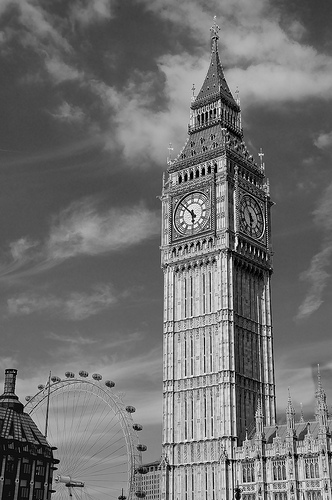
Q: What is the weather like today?
A: It is cloudy.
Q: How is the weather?
A: It is cloudy.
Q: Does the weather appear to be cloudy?
A: Yes, it is cloudy.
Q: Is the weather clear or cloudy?
A: It is cloudy.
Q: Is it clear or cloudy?
A: It is cloudy.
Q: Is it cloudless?
A: No, it is cloudy.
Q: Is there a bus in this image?
A: No, there are no buses.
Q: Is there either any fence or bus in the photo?
A: No, there are no buses or fences.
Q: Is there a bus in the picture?
A: No, there are no buses.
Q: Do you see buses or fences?
A: No, there are no buses or fences.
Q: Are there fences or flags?
A: No, there are no fences or flags.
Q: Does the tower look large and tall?
A: Yes, the tower is large and tall.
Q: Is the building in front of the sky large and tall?
A: Yes, the tower is large and tall.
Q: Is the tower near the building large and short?
A: No, the tower is large but tall.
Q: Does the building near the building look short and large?
A: No, the tower is large but tall.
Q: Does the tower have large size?
A: Yes, the tower is large.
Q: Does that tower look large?
A: Yes, the tower is large.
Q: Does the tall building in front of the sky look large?
A: Yes, the tower is large.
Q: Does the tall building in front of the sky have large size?
A: Yes, the tower is large.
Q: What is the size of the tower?
A: The tower is large.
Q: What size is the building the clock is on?
A: The tower is large.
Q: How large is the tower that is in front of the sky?
A: The tower is large.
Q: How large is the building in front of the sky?
A: The tower is large.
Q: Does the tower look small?
A: No, the tower is large.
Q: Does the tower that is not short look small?
A: No, the tower is large.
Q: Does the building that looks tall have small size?
A: No, the tower is large.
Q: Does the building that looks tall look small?
A: No, the tower is large.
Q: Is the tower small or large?
A: The tower is large.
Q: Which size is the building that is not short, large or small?
A: The tower is large.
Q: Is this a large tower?
A: Yes, this is a large tower.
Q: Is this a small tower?
A: No, this is a large tower.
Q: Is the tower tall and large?
A: Yes, the tower is tall and large.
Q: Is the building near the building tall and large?
A: Yes, the tower is tall and large.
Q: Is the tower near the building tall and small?
A: No, the tower is tall but large.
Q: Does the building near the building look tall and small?
A: No, the tower is tall but large.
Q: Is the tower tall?
A: Yes, the tower is tall.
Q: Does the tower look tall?
A: Yes, the tower is tall.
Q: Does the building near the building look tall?
A: Yes, the tower is tall.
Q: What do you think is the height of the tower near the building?
A: The tower is tall.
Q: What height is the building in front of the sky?
A: The tower is tall.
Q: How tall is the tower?
A: The tower is tall.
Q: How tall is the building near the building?
A: The tower is tall.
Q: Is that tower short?
A: No, the tower is tall.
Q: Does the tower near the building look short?
A: No, the tower is tall.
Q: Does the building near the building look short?
A: No, the tower is tall.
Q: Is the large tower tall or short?
A: The tower is tall.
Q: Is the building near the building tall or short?
A: The tower is tall.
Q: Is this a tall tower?
A: Yes, this is a tall tower.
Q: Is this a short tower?
A: No, this is a tall tower.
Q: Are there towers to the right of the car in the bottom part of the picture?
A: Yes, there is a tower to the right of the car.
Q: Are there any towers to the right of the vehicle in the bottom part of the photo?
A: Yes, there is a tower to the right of the car.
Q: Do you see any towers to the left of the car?
A: No, the tower is to the right of the car.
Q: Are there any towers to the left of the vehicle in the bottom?
A: No, the tower is to the right of the car.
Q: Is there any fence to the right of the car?
A: No, there is a tower to the right of the car.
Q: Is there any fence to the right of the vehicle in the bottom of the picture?
A: No, there is a tower to the right of the car.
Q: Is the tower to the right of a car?
A: Yes, the tower is to the right of a car.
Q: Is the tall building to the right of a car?
A: Yes, the tower is to the right of a car.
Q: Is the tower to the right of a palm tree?
A: No, the tower is to the right of a car.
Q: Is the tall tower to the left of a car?
A: No, the tower is to the right of a car.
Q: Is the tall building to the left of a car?
A: No, the tower is to the right of a car.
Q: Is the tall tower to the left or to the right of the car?
A: The tower is to the right of the car.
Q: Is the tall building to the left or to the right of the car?
A: The tower is to the right of the car.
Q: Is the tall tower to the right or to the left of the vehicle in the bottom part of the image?
A: The tower is to the right of the car.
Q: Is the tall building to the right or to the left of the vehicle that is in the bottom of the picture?
A: The tower is to the right of the car.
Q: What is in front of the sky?
A: The tower is in front of the sky.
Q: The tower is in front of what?
A: The tower is in front of the sky.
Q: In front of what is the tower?
A: The tower is in front of the sky.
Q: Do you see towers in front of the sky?
A: Yes, there is a tower in front of the sky.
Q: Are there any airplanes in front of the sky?
A: No, there is a tower in front of the sky.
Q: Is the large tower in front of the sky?
A: Yes, the tower is in front of the sky.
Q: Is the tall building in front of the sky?
A: Yes, the tower is in front of the sky.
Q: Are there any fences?
A: No, there are no fences.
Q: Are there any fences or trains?
A: No, there are no fences or trains.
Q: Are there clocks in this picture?
A: Yes, there is a clock.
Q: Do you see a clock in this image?
A: Yes, there is a clock.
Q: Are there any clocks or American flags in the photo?
A: Yes, there is a clock.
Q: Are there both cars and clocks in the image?
A: Yes, there are both a clock and a car.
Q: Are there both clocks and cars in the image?
A: Yes, there are both a clock and a car.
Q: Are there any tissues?
A: No, there are no tissues.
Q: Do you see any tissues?
A: No, there are no tissues.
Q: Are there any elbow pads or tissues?
A: No, there are no tissues or elbow pads.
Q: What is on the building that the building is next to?
A: The clock is on the tower.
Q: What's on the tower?
A: The clock is on the tower.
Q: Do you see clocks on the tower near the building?
A: Yes, there is a clock on the tower.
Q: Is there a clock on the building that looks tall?
A: Yes, there is a clock on the tower.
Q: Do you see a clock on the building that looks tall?
A: Yes, there is a clock on the tower.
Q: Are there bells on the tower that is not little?
A: No, there is a clock on the tower.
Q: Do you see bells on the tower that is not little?
A: No, there is a clock on the tower.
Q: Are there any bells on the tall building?
A: No, there is a clock on the tower.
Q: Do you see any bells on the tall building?
A: No, there is a clock on the tower.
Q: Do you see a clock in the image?
A: Yes, there is a clock.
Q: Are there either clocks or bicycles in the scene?
A: Yes, there is a clock.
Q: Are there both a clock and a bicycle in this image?
A: No, there is a clock but no bicycles.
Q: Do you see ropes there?
A: No, there are no ropes.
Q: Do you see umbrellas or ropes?
A: No, there are no ropes or umbrellas.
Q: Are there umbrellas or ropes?
A: No, there are no ropes or umbrellas.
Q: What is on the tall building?
A: The clock is on the tower.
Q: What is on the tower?
A: The clock is on the tower.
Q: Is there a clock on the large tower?
A: Yes, there is a clock on the tower.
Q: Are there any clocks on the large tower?
A: Yes, there is a clock on the tower.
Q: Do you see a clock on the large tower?
A: Yes, there is a clock on the tower.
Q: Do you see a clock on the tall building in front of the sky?
A: Yes, there is a clock on the tower.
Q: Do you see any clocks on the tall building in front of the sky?
A: Yes, there is a clock on the tower.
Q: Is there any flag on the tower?
A: No, there is a clock on the tower.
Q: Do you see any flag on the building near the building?
A: No, there is a clock on the tower.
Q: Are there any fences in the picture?
A: No, there are no fences.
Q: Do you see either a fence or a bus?
A: No, there are no fences or buses.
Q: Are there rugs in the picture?
A: No, there are no rugs.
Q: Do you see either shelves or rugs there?
A: No, there are no rugs or shelves.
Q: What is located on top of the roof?
A: The decoration is on top of the roof.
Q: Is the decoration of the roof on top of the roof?
A: Yes, the decoration is on top of the roof.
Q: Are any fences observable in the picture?
A: No, there are no fences.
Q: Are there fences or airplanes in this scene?
A: No, there are no fences or airplanes.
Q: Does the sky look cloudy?
A: Yes, the sky is cloudy.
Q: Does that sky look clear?
A: No, the sky is cloudy.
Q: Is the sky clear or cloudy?
A: The sky is cloudy.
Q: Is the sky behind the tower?
A: Yes, the sky is behind the tower.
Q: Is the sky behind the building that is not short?
A: Yes, the sky is behind the tower.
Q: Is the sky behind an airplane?
A: No, the sky is behind the tower.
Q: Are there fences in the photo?
A: No, there are no fences.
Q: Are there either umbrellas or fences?
A: No, there are no fences or umbrellas.